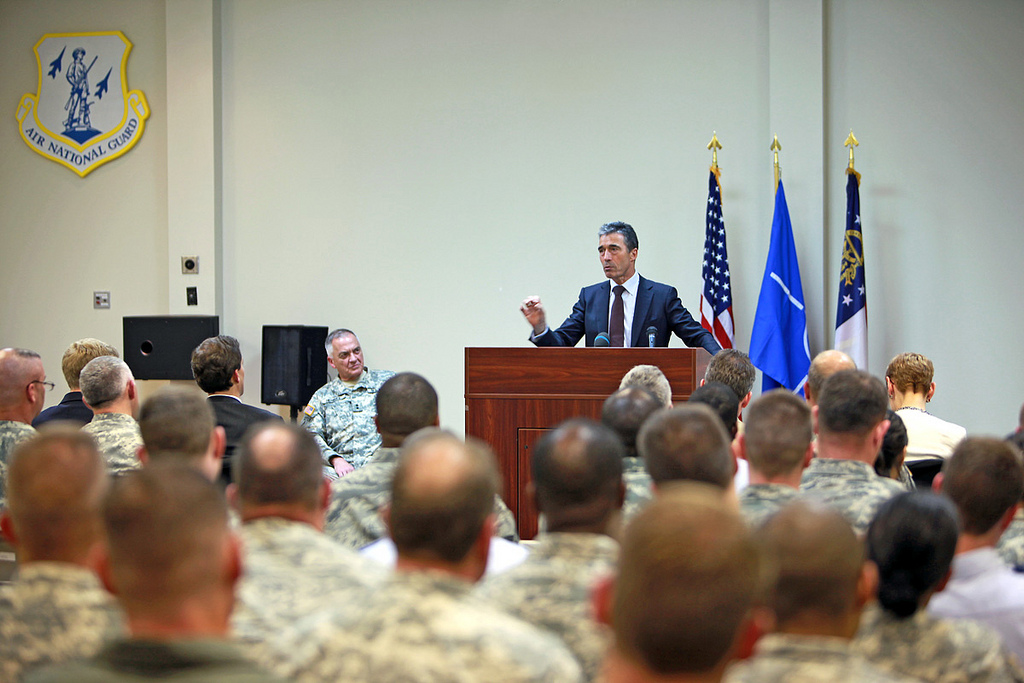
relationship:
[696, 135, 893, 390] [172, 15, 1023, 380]
flags near wall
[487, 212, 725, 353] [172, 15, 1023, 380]
man near wall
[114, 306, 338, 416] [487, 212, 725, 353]
speakers near man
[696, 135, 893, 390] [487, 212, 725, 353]
flags near man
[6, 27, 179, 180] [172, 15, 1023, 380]
logo on wall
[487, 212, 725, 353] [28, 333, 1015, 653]
man speaking to people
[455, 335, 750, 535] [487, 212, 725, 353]
podium in front of man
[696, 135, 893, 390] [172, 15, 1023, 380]
flags against wall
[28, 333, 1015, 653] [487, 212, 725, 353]
people in front of man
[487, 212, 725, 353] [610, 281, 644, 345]
man in tie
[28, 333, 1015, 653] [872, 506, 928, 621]
people have hair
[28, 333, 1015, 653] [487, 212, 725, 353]
people near man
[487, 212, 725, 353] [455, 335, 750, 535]
man behind podium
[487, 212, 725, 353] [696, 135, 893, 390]
man near flags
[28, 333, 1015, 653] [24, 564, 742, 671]
people in uniforms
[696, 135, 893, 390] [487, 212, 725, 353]
flags behind man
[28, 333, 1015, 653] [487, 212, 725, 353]
people looking at man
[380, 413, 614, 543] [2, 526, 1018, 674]
man seen from back